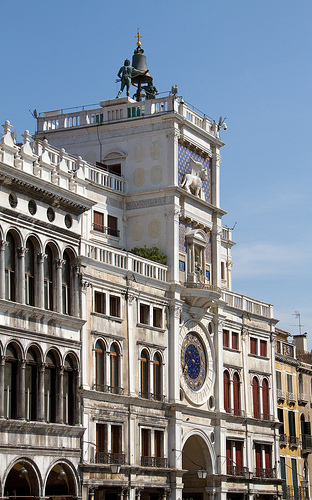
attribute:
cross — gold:
[134, 30, 145, 46]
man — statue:
[118, 60, 135, 96]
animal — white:
[181, 158, 211, 194]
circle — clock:
[182, 334, 208, 390]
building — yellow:
[3, 112, 303, 491]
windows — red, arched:
[223, 330, 277, 477]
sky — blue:
[215, 14, 310, 63]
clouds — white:
[236, 218, 302, 265]